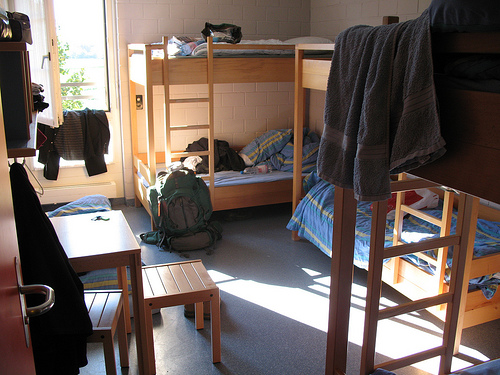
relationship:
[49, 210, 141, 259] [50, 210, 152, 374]
surface of table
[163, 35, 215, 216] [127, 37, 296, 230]
ladder of bed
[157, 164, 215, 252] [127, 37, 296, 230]
pack propped against bed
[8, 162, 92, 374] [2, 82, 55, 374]
jacket hanging from door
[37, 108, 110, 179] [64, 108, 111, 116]
jacket laying on windowsill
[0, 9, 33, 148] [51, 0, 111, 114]
shirts hung near window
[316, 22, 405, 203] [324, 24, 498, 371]
towel hanging on a bed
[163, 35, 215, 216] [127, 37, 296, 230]
ladder to a bed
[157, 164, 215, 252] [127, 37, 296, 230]
pack against bed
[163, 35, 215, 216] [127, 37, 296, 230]
ladder to bed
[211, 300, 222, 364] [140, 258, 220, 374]
leg of chair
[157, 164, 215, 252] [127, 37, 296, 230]
pack next to bed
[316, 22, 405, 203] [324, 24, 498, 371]
towel hanging off of bed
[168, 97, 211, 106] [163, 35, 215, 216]
step of ladder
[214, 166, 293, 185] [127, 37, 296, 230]
sheet on bed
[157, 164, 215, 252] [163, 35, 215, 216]
pack laying against ladder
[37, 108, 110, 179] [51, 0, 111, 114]
jacket hanging out window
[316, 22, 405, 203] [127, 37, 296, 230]
towel hanging from bed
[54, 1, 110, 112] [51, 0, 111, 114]
light coming from window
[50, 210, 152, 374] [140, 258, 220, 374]
table with chair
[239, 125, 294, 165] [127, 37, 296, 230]
pillow on bed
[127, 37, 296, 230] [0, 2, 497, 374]
bed in picture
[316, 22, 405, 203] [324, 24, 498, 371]
towel on bed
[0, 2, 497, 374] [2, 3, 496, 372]
picture taken during day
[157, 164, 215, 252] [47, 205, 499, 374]
pack on flooring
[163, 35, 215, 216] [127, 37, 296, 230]
ladder against bed